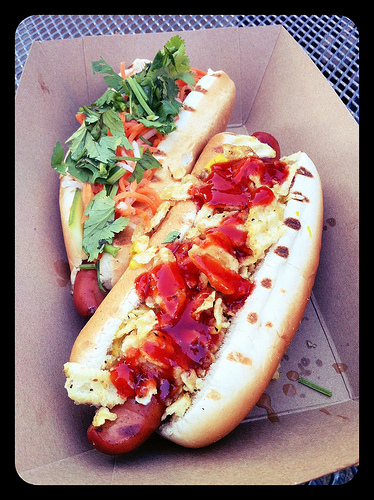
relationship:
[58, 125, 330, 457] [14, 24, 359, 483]
hot dog in a tray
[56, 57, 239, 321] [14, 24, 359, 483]
hot dog in a tray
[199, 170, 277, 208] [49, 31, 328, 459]
ketchup on hotdog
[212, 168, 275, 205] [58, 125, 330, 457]
tomato on hot dog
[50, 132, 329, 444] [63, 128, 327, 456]
hot dog in a bread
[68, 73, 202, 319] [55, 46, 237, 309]
hot dog in a bun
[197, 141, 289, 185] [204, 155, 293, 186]
mustard on ketchup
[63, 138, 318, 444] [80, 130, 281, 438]
bread of hotdog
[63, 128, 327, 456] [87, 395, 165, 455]
bread of a hotdog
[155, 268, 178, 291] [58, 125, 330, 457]
sauce on a hot dog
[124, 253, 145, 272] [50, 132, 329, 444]
mustard on a hot dog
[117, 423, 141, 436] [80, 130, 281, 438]
grill mark on a hotdog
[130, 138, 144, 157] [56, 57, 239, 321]
onion on a hot dog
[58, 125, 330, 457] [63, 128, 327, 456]
hot dog on bread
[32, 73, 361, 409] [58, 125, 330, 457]
tray holding hot dog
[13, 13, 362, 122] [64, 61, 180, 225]
table holding hotdog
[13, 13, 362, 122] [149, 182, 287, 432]
table holding hotdog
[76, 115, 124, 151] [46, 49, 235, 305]
cilantro on hot dog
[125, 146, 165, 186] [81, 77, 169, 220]
leafy greens on top of hotdog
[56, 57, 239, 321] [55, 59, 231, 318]
hot dog in bun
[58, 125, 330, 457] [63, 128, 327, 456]
hot dog in bread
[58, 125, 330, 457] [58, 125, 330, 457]
hot dog in hot dog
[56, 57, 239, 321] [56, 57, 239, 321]
hot dog in hot dog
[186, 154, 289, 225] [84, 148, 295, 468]
ketchup in hot dog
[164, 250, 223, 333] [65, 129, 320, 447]
topping on hot dog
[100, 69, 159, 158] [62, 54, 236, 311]
topping on hot dog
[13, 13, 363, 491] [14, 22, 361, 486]
table next to tray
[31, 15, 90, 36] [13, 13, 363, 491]
holes in table